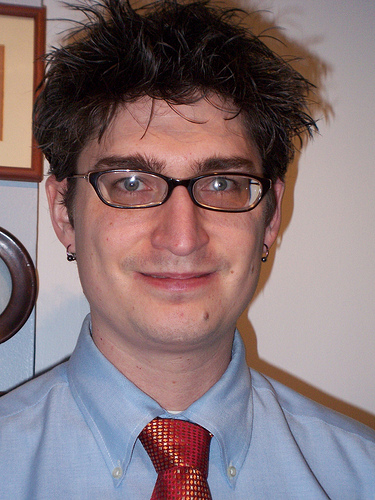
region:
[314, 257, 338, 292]
part of a wall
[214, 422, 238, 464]
part of a collar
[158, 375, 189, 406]
part of a neck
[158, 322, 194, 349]
chin of a man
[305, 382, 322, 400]
part of a shade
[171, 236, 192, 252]
nose of a man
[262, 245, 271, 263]
part of an earring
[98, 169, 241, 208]
spectacle of a man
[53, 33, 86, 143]
hair of the man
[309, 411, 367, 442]
shoulder of the man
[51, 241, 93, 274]
black earrings in man's ear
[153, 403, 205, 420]
small edge of white tee shirt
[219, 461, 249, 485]
small white buttons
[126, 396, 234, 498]
red tie around man's neck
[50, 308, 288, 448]
blue shirt collar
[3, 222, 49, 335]
round shiny black circle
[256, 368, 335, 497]
long crease in man's shirt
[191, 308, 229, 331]
small black mole on face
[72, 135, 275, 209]
man's bushy eye brows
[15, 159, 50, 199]
brown edge on painting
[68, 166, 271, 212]
black glasses on face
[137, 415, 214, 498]
red tie knotted on man's neck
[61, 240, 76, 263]
earring in man's right ear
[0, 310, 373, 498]
blue button down shirt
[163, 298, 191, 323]
pimple on man's chin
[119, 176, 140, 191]
the man has blue eyes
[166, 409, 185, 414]
sliver of white t-shirt at man's neck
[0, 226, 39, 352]
brown picture frame on wall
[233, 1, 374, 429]
shadow on wall behind man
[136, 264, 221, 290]
man smiling for the camera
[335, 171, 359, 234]
part of a wall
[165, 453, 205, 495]
part of a tie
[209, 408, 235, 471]
part of a collar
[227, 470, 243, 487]
part of a button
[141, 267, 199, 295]
mouth of a man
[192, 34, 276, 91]
hair of the man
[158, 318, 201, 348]
chin of the man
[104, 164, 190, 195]
spectacles of the man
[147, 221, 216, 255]
nose of the man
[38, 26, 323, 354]
The man is smiling.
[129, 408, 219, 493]
The man is wearing a red tie.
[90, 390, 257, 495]
Two buttons hold the collar down.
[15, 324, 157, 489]
The shirt is light blue.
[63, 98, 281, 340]
The man has a shaved face.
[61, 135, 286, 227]
The man is wearing glasses.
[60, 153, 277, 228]
The glasses are made from plastic and metal.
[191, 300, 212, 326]
A mole.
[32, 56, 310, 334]
The man has pierced ears.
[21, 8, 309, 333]
The man has dark brown hair.